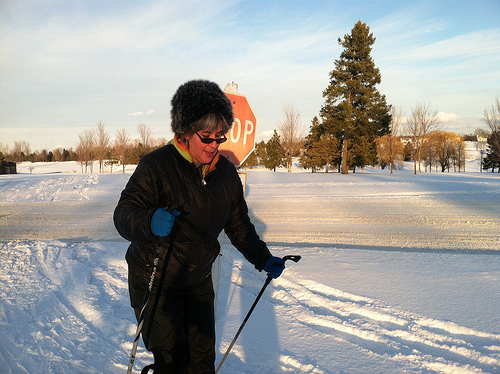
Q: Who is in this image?
A: A woman.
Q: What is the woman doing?
A: Skiing.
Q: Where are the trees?
A: Behind the woman.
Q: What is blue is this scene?
A: The woman's gloves.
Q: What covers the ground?
A: Snow.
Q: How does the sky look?
A: Cloudy.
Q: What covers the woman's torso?
A: A black jacket.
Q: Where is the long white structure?
A: Behind and to the left of the woman.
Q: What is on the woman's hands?
A: Gloves.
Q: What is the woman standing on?
A: Snow.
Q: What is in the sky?
A: Clouds.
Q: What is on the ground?
A: Snow.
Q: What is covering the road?
A: Snow.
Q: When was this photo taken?
A: Daytime.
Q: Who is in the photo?
A: A woman.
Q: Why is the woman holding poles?
A: She is skiing.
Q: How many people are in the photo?
A: One.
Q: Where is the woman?
A: Just in front of a stop sign.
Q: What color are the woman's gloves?
A: Blue.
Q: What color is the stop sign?
A: Red.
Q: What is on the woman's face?
A: Sunglasses.